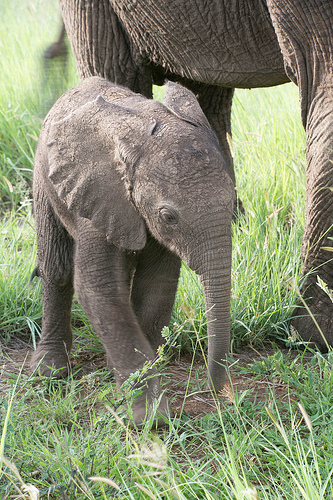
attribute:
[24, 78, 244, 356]
elephant — young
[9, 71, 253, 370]
elephant — young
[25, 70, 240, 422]
elephant — young, baby, mother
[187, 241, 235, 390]
nose — long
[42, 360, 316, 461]
grass — sticking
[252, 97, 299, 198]
grass — long, green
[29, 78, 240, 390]
elephant — baby, young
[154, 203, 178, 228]
eye — black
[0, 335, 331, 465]
dirt — brown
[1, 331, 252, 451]
dirt — brown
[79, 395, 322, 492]
grass — long, green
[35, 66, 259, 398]
elephant — large, grey, mother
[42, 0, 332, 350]
elephant — adult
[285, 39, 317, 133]
kin — elephant, hanging, loose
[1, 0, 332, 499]
grass — green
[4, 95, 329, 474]
grass — green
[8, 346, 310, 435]
patch — barren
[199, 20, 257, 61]
skin — grey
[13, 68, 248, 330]
elephant — baby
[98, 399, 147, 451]
tuft — whitish